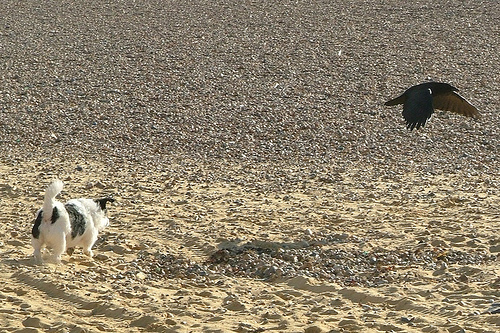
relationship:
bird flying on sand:
[384, 80, 481, 132] [2, 0, 499, 331]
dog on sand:
[25, 176, 117, 270] [2, 0, 499, 331]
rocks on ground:
[209, 223, 312, 286] [198, 198, 317, 331]